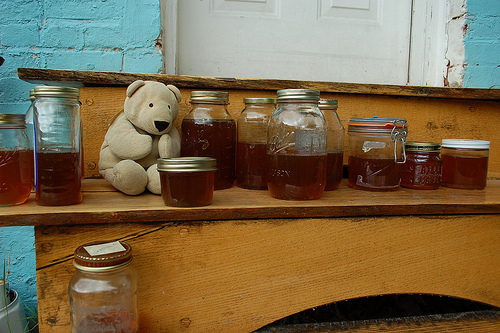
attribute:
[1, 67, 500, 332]
wood — brown, being used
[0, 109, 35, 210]
jar — glass, clear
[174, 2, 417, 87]
door — white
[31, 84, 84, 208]
jar — half full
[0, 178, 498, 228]
shelf — wood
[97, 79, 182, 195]
bear — toy, beige, old, stuffed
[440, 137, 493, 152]
lid — white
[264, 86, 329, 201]
jar — half filled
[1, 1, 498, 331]
wall — brick, blue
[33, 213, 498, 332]
step bottom — arched, cracked